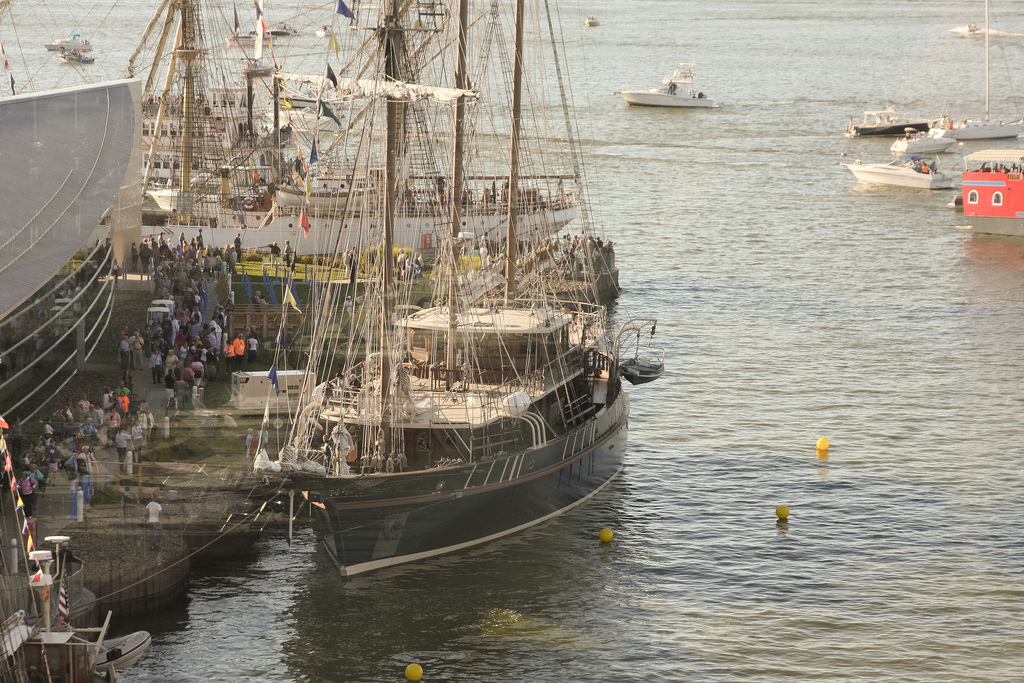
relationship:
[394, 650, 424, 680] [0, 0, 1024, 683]
yellow ball in harbor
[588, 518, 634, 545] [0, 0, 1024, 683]
yellow ball in harbor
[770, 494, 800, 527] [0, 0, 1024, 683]
yellow ball in harbor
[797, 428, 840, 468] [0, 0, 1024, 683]
yellow ball in harbor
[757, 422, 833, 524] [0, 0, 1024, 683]
yellowballs in harbor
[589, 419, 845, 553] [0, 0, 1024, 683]
yellowballs in harbor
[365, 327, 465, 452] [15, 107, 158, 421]
wall on building